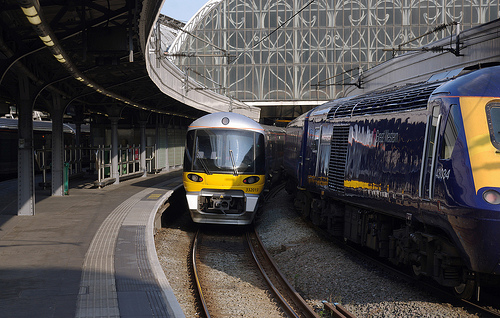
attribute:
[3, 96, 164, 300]
station — empty, ornate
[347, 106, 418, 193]
window — big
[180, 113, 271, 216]
train — next, blue, numbered, yellow, silver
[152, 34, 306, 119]
walkway — above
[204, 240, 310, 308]
railroad — covered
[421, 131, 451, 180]
handles — silver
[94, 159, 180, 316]
platform — lighted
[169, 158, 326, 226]
engine — yellow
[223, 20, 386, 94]
buliding — decorative, curved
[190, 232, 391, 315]
tracks — iron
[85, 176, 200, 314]
platfomr — curved